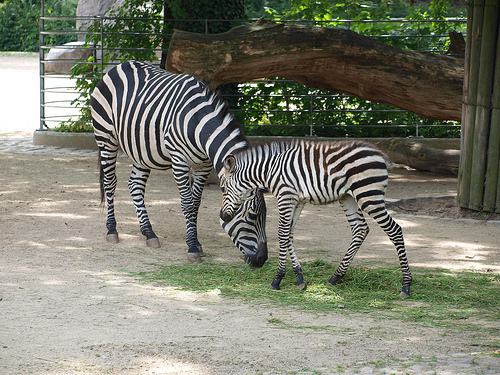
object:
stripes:
[218, 145, 412, 283]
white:
[344, 199, 353, 212]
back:
[222, 143, 412, 171]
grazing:
[0, 62, 500, 331]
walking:
[219, 138, 413, 299]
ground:
[0, 309, 498, 375]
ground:
[128, 242, 499, 337]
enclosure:
[0, 0, 500, 375]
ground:
[356, 102, 486, 154]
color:
[141, 253, 500, 312]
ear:
[223, 154, 237, 175]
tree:
[456, 22, 500, 212]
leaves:
[372, 102, 462, 137]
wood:
[344, 71, 415, 106]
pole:
[39, 0, 44, 131]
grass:
[130, 248, 500, 374]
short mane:
[286, 137, 393, 166]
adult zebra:
[89, 60, 269, 270]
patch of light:
[69, 269, 223, 311]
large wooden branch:
[164, 17, 465, 122]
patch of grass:
[99, 245, 500, 341]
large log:
[375, 137, 460, 177]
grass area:
[86, 247, 499, 374]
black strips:
[110, 61, 195, 162]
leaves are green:
[66, 0, 163, 124]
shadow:
[327, 265, 500, 375]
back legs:
[334, 185, 412, 289]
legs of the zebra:
[164, 127, 215, 245]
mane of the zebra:
[199, 82, 251, 153]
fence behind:
[39, 0, 164, 129]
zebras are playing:
[90, 59, 414, 299]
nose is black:
[250, 243, 268, 268]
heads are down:
[218, 188, 269, 269]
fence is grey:
[35, 0, 468, 138]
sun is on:
[408, 240, 500, 277]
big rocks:
[43, 0, 164, 75]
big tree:
[160, 0, 250, 135]